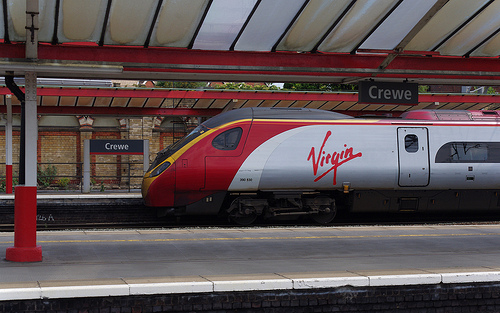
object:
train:
[140, 105, 500, 223]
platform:
[0, 224, 499, 312]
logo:
[306, 127, 365, 187]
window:
[435, 140, 499, 163]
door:
[396, 124, 433, 189]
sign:
[90, 139, 140, 154]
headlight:
[150, 159, 172, 179]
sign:
[360, 80, 420, 106]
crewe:
[103, 142, 129, 152]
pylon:
[5, 186, 45, 265]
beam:
[4, 96, 14, 190]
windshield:
[167, 124, 207, 148]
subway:
[0, 202, 134, 228]